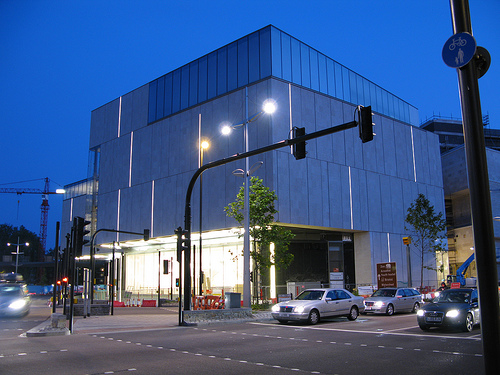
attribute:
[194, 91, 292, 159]
lights — on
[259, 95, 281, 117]
light — white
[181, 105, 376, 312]
light pole — black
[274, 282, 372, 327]
car — grey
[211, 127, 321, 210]
signals — black, metal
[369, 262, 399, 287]
sign — large, red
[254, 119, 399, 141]
light — traffic light, metal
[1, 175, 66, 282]
crane — metal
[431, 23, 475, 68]
sign — blue, metal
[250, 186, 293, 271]
leaves — green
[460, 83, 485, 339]
pole — black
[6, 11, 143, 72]
sky — clear, blue